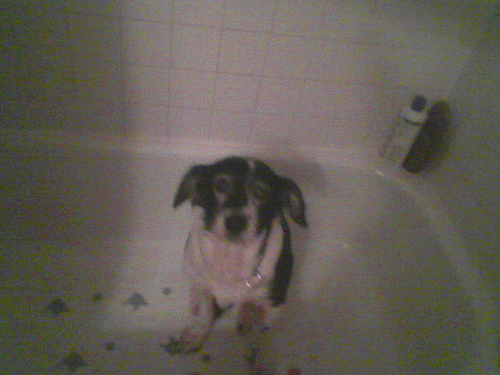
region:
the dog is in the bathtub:
[132, 135, 335, 369]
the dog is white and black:
[138, 112, 391, 356]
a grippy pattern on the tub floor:
[16, 265, 303, 374]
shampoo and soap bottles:
[380, 58, 489, 198]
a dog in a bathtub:
[129, 116, 339, 372]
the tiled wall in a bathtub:
[0, 0, 433, 152]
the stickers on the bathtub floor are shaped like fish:
[23, 267, 182, 374]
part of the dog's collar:
[212, 234, 307, 303]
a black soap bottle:
[403, 80, 468, 196]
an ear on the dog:
[287, 182, 306, 221]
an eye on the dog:
[250, 183, 265, 202]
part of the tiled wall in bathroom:
[162, 14, 323, 112]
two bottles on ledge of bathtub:
[380, 87, 453, 173]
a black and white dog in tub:
[172, 143, 298, 374]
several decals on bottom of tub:
[78, 268, 159, 332]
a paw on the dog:
[169, 335, 194, 357]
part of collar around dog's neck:
[245, 225, 274, 288]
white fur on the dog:
[198, 247, 236, 282]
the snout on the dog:
[227, 218, 246, 230]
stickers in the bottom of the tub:
[40, 286, 167, 372]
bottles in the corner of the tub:
[373, 82, 447, 184]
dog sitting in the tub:
[130, 172, 305, 374]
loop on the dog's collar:
[237, 268, 264, 295]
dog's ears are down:
[144, 148, 311, 253]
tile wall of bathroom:
[59, 21, 309, 120]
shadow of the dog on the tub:
[274, 142, 327, 201]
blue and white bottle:
[378, 88, 422, 175]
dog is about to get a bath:
[164, 138, 299, 360]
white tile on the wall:
[40, 9, 371, 130]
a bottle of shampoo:
[385, 90, 460, 170]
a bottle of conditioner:
[381, 92, 433, 159]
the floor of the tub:
[33, 276, 185, 357]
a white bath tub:
[28, 131, 472, 364]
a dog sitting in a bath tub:
[138, 158, 299, 333]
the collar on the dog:
[226, 244, 268, 282]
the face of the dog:
[162, 148, 307, 240]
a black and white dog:
[147, 147, 317, 363]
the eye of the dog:
[213, 173, 226, 188]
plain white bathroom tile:
[67, 0, 132, 15]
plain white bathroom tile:
[121, 2, 171, 32]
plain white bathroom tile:
[68, 8, 123, 63]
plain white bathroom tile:
[113, 12, 172, 70]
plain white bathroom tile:
[206, 23, 274, 87]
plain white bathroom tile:
[266, 18, 314, 83]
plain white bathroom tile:
[314, 29, 354, 88]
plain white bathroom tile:
[348, 35, 403, 92]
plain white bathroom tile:
[159, 91, 214, 142]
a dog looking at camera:
[13, 40, 495, 355]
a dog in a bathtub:
[17, 43, 464, 342]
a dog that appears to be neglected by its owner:
[11, 26, 447, 369]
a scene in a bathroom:
[36, 47, 495, 336]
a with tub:
[26, 115, 458, 340]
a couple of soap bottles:
[347, 80, 489, 334]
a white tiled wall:
[23, 30, 491, 183]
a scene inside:
[106, 55, 426, 305]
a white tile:
[208, 63, 280, 121]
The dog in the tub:
[167, 151, 312, 361]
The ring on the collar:
[242, 270, 263, 290]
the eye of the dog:
[215, 177, 231, 194]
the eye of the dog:
[250, 180, 270, 197]